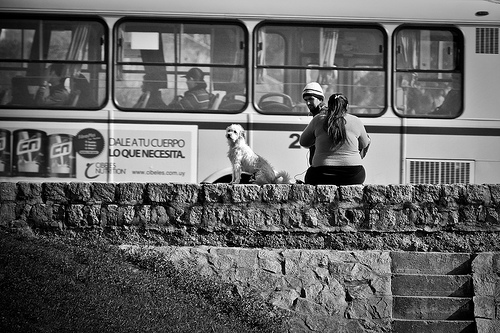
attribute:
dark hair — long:
[317, 86, 357, 151]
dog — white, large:
[220, 114, 292, 189]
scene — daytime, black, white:
[1, 2, 492, 332]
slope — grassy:
[2, 223, 295, 332]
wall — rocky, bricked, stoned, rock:
[2, 177, 499, 255]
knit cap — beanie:
[295, 79, 331, 98]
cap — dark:
[175, 66, 210, 80]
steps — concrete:
[385, 246, 480, 332]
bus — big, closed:
[2, 2, 492, 191]